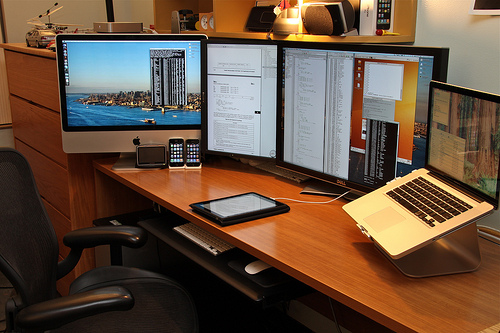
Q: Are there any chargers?
A: No, there are no chargers.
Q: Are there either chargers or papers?
A: No, there are no chargers or papers.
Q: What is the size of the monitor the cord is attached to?
A: The monitor is large.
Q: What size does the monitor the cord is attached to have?
A: The monitor has large size.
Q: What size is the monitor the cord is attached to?
A: The monitor is large.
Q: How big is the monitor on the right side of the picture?
A: The monitor is large.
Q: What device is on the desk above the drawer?
A: The device is a monitor.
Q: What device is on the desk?
A: The device is a monitor.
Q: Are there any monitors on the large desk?
A: Yes, there is a monitor on the desk.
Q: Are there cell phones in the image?
A: Yes, there is a cell phone.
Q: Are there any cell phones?
A: Yes, there is a cell phone.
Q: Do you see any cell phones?
A: Yes, there is a cell phone.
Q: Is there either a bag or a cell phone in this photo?
A: Yes, there is a cell phone.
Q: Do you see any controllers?
A: No, there are no controllers.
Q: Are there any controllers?
A: No, there are no controllers.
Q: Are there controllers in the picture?
A: No, there are no controllers.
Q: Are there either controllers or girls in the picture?
A: No, there are no controllers or girls.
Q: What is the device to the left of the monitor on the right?
A: The device is a cell phone.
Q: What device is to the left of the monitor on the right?
A: The device is a cell phone.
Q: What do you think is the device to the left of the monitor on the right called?
A: The device is a cell phone.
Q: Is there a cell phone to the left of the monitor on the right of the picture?
A: Yes, there is a cell phone to the left of the monitor.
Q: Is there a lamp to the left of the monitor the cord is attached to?
A: No, there is a cell phone to the left of the monitor.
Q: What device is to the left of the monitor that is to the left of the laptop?
A: The device is a cell phone.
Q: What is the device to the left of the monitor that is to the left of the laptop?
A: The device is a cell phone.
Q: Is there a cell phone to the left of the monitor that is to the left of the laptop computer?
A: Yes, there is a cell phone to the left of the monitor.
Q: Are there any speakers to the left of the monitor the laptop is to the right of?
A: No, there is a cell phone to the left of the monitor.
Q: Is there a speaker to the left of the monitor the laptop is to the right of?
A: No, there is a cell phone to the left of the monitor.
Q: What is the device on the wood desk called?
A: The device is a cell phone.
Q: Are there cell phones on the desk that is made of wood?
A: Yes, there is a cell phone on the desk.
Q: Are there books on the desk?
A: No, there is a cell phone on the desk.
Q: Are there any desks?
A: Yes, there is a desk.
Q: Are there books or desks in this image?
A: Yes, there is a desk.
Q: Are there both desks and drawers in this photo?
A: Yes, there are both a desk and a drawer.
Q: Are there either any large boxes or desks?
A: Yes, there is a large desk.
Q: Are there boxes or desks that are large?
A: Yes, the desk is large.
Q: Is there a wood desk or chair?
A: Yes, there is a wood desk.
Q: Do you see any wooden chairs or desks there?
A: Yes, there is a wood desk.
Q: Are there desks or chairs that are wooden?
A: Yes, the desk is wooden.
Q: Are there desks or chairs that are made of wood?
A: Yes, the desk is made of wood.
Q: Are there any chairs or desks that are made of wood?
A: Yes, the desk is made of wood.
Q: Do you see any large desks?
A: Yes, there is a large desk.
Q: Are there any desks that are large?
A: Yes, there is a desk that is large.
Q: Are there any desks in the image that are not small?
A: Yes, there is a large desk.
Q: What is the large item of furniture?
A: The piece of furniture is a desk.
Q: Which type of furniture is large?
A: The furniture is a desk.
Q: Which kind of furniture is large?
A: The furniture is a desk.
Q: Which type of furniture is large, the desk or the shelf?
A: The desk is large.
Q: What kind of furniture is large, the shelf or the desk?
A: The desk is large.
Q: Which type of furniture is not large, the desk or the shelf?
A: The shelf is not large.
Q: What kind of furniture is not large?
A: The furniture is a shelf.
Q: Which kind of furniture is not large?
A: The furniture is a shelf.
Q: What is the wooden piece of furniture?
A: The piece of furniture is a desk.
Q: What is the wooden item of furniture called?
A: The piece of furniture is a desk.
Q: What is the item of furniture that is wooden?
A: The piece of furniture is a desk.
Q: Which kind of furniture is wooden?
A: The furniture is a desk.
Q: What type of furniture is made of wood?
A: The furniture is a desk.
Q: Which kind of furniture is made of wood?
A: The furniture is a desk.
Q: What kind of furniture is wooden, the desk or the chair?
A: The desk is wooden.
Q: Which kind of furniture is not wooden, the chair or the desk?
A: The chair is not wooden.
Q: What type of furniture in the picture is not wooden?
A: The furniture is a chair.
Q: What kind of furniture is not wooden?
A: The furniture is a chair.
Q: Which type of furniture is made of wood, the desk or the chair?
A: The desk is made of wood.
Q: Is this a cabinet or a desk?
A: This is a desk.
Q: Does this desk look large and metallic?
A: No, the desk is large but wooden.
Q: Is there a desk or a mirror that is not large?
A: No, there is a desk but it is large.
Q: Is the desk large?
A: Yes, the desk is large.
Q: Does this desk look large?
A: Yes, the desk is large.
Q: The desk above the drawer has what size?
A: The desk is large.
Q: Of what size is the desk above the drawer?
A: The desk is large.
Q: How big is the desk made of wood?
A: The desk is large.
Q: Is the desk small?
A: No, the desk is large.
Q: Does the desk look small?
A: No, the desk is large.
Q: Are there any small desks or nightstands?
A: No, there is a desk but it is large.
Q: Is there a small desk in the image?
A: No, there is a desk but it is large.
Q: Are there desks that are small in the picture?
A: No, there is a desk but it is large.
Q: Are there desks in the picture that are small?
A: No, there is a desk but it is large.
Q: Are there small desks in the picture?
A: No, there is a desk but it is large.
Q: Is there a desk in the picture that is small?
A: No, there is a desk but it is large.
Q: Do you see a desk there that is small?
A: No, there is a desk but it is large.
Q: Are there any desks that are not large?
A: No, there is a desk but it is large.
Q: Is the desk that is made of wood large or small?
A: The desk is large.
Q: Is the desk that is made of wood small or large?
A: The desk is large.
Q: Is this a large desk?
A: Yes, this is a large desk.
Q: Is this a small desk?
A: No, this is a large desk.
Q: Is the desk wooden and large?
A: Yes, the desk is wooden and large.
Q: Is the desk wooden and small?
A: No, the desk is wooden but large.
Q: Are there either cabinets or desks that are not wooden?
A: No, there is a desk but it is wooden.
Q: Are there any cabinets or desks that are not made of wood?
A: No, there is a desk but it is made of wood.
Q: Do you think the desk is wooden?
A: Yes, the desk is wooden.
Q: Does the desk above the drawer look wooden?
A: Yes, the desk is wooden.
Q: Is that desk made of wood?
A: Yes, the desk is made of wood.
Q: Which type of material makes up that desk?
A: The desk is made of wood.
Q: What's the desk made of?
A: The desk is made of wood.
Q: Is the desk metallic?
A: No, the desk is wooden.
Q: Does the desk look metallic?
A: No, the desk is wooden.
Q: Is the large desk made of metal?
A: No, the desk is made of wood.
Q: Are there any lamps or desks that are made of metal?
A: No, there is a desk but it is made of wood.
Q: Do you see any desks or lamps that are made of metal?
A: No, there is a desk but it is made of wood.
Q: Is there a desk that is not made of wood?
A: No, there is a desk but it is made of wood.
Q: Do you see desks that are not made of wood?
A: No, there is a desk but it is made of wood.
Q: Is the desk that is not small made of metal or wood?
A: The desk is made of wood.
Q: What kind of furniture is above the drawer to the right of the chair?
A: The piece of furniture is a desk.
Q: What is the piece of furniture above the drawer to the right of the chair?
A: The piece of furniture is a desk.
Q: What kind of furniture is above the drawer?
A: The piece of furniture is a desk.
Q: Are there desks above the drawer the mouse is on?
A: Yes, there is a desk above the drawer.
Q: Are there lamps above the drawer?
A: No, there is a desk above the drawer.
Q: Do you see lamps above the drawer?
A: No, there is a desk above the drawer.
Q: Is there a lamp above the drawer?
A: No, there is a desk above the drawer.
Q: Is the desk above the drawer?
A: Yes, the desk is above the drawer.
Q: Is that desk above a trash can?
A: No, the desk is above the drawer.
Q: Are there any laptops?
A: Yes, there is a laptop.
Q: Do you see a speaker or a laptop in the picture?
A: Yes, there is a laptop.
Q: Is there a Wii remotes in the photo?
A: No, there are no Wii controllers.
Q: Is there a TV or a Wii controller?
A: No, there are no Wii controllers or televisions.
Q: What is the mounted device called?
A: The device is a laptop.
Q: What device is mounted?
A: The device is a laptop.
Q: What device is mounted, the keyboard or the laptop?
A: The laptop is mounted.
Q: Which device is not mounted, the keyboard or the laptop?
A: The keyboard is not mounted.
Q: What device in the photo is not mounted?
A: The device is a keyboard.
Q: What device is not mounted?
A: The device is a keyboard.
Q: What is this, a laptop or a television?
A: This is a laptop.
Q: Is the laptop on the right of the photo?
A: Yes, the laptop is on the right of the image.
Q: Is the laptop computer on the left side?
A: No, the laptop computer is on the right of the image.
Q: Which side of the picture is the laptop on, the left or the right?
A: The laptop is on the right of the image.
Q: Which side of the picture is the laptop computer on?
A: The laptop computer is on the right of the image.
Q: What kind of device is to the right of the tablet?
A: The device is a laptop.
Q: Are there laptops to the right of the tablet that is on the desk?
A: Yes, there is a laptop to the right of the tablet.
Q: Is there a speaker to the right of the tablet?
A: No, there is a laptop to the right of the tablet.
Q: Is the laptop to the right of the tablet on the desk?
A: Yes, the laptop is to the right of the tablet.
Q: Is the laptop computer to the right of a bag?
A: No, the laptop computer is to the right of the tablet.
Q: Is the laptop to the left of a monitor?
A: No, the laptop is to the right of a monitor.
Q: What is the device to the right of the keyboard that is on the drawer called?
A: The device is a laptop.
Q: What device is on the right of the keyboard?
A: The device is a laptop.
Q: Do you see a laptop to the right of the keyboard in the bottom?
A: Yes, there is a laptop to the right of the keyboard.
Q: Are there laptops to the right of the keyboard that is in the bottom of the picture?
A: Yes, there is a laptop to the right of the keyboard.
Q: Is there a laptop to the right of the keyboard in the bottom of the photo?
A: Yes, there is a laptop to the right of the keyboard.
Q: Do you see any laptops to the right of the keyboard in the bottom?
A: Yes, there is a laptop to the right of the keyboard.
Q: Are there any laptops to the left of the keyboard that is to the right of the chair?
A: No, the laptop is to the right of the keyboard.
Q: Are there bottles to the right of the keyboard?
A: No, there is a laptop to the right of the keyboard.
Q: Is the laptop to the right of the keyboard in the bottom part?
A: Yes, the laptop is to the right of the keyboard.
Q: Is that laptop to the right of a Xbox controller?
A: No, the laptop is to the right of the keyboard.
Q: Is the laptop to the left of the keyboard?
A: No, the laptop is to the right of the keyboard.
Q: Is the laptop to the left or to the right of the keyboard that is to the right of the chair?
A: The laptop is to the right of the keyboard.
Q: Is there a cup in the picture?
A: No, there are no cups.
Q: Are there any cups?
A: No, there are no cups.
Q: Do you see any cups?
A: No, there are no cups.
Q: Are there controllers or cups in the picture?
A: No, there are no cups or controllers.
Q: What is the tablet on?
A: The tablet is on the desk.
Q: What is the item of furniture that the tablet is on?
A: The piece of furniture is a desk.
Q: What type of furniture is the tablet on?
A: The tablet is on the desk.